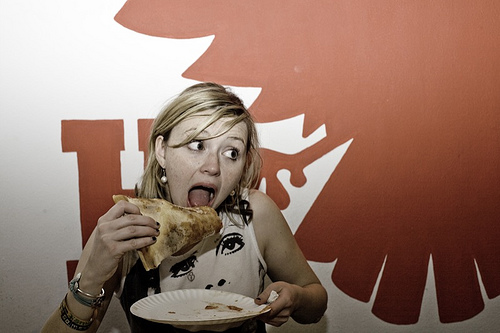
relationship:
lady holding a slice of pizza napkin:
[40, 76, 327, 331] [264, 292, 275, 299]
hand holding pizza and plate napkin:
[256, 271, 302, 326] [264, 292, 275, 299]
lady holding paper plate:
[40, 76, 327, 331] [128, 285, 270, 325]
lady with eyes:
[40, 76, 327, 331] [178, 127, 250, 159]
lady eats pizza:
[40, 76, 327, 331] [108, 195, 232, 271]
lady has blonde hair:
[40, 76, 327, 331] [150, 84, 245, 131]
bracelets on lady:
[66, 271, 115, 310] [40, 76, 327, 331]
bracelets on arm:
[58, 294, 95, 331] [42, 221, 121, 329]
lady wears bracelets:
[40, 76, 327, 331] [58, 294, 95, 331]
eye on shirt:
[172, 257, 194, 277] [118, 182, 270, 331]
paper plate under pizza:
[128, 285, 270, 325] [110, 180, 222, 280]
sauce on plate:
[204, 300, 248, 315] [125, 284, 276, 331]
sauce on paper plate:
[223, 301, 247, 318] [128, 285, 270, 325]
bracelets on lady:
[51, 265, 107, 333] [40, 76, 327, 331]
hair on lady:
[133, 81, 266, 205] [40, 76, 327, 331]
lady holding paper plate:
[40, 76, 327, 331] [128, 286, 275, 330]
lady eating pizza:
[40, 76, 327, 331] [108, 195, 232, 271]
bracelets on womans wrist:
[51, 265, 107, 333] [68, 267, 116, 313]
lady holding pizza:
[40, 76, 327, 331] [108, 195, 232, 271]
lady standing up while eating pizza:
[40, 76, 327, 331] [108, 195, 232, 271]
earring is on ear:
[161, 164, 168, 187] [153, 133, 165, 169]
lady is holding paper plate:
[40, 76, 327, 331] [128, 285, 270, 325]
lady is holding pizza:
[40, 76, 327, 331] [108, 195, 232, 271]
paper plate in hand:
[128, 285, 270, 325] [256, 271, 302, 326]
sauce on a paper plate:
[204, 300, 248, 315] [122, 283, 275, 324]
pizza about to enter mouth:
[108, 195, 232, 271] [180, 181, 222, 208]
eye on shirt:
[214, 232, 246, 257] [97, 181, 269, 330]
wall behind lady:
[2, 5, 472, 325] [40, 76, 327, 331]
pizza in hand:
[108, 195, 232, 271] [85, 198, 160, 283]